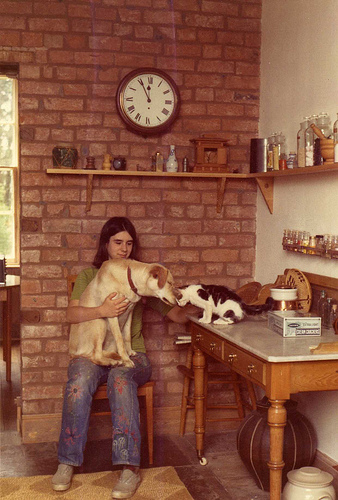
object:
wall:
[0, 0, 263, 448]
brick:
[26, 15, 70, 34]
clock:
[115, 66, 181, 135]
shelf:
[46, 167, 247, 214]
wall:
[255, 0, 338, 467]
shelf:
[246, 162, 338, 214]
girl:
[53, 216, 152, 498]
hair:
[92, 217, 136, 269]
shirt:
[70, 262, 174, 353]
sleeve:
[145, 295, 175, 318]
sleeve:
[71, 268, 96, 301]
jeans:
[57, 353, 152, 468]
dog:
[68, 258, 182, 367]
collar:
[127, 266, 147, 297]